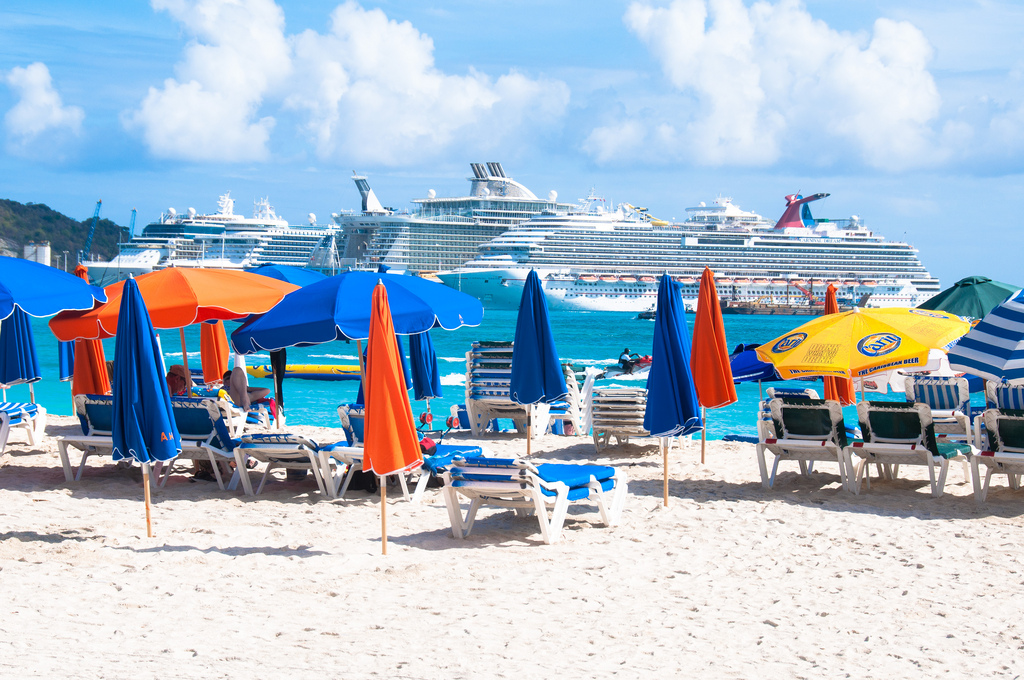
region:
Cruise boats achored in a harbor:
[170, 219, 781, 267]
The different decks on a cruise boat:
[577, 237, 666, 264]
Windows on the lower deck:
[581, 286, 626, 297]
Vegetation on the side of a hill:
[3, 207, 49, 231]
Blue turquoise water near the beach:
[558, 321, 639, 345]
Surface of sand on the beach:
[517, 605, 701, 676]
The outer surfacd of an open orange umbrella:
[153, 269, 251, 307]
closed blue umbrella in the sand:
[104, 275, 181, 539]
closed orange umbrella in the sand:
[357, 274, 425, 557]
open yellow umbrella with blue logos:
[754, 303, 976, 384]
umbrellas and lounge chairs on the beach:
[0, 250, 1021, 563]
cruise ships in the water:
[81, 160, 944, 313]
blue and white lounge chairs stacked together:
[445, 443, 629, 546]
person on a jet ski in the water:
[597, 345, 654, 384]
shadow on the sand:
[98, 541, 343, 561]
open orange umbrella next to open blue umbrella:
[49, 265, 489, 355]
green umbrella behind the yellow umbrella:
[916, 274, 1021, 325]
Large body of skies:
[179, 29, 408, 121]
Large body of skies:
[63, 47, 338, 166]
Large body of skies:
[449, 9, 735, 153]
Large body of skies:
[68, 37, 299, 175]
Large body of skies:
[82, 10, 318, 157]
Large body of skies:
[531, 31, 757, 149]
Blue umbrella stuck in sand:
[639, 260, 703, 505]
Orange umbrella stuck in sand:
[362, 271, 423, 553]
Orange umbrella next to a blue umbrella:
[42, 260, 296, 384]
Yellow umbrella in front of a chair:
[751, 304, 976, 390]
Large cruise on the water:
[435, 195, 944, 310]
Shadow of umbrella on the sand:
[115, 537, 341, 557]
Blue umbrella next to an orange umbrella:
[0, 252, 114, 326]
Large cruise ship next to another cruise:
[280, 158, 587, 276]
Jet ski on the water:
[596, 348, 654, 380]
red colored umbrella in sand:
[352, 272, 426, 492]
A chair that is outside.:
[967, 380, 1022, 507]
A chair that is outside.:
[850, 396, 981, 502]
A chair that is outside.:
[755, 393, 857, 492]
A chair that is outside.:
[445, 452, 626, 538]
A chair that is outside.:
[233, 430, 328, 498]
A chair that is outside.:
[147, 396, 246, 495]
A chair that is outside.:
[43, 390, 116, 480]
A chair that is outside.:
[0, 397, 48, 451]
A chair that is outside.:
[461, 387, 594, 436]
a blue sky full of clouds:
[0, 0, 1018, 291]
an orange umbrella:
[359, 279, 420, 556]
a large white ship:
[312, 157, 936, 316]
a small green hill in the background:
[5, 195, 126, 275]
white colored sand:
[0, 429, 1021, 673]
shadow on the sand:
[622, 471, 1022, 522]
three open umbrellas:
[3, 250, 491, 352]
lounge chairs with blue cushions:
[442, 456, 623, 540]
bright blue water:
[0, 307, 998, 413]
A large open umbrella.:
[347, 279, 468, 562]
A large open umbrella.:
[495, 266, 569, 467]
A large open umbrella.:
[640, 254, 710, 488]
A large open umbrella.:
[691, 273, 739, 458]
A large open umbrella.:
[768, 283, 933, 400]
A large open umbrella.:
[948, 280, 1021, 356]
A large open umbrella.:
[907, 272, 994, 324]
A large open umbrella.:
[76, 266, 323, 334]